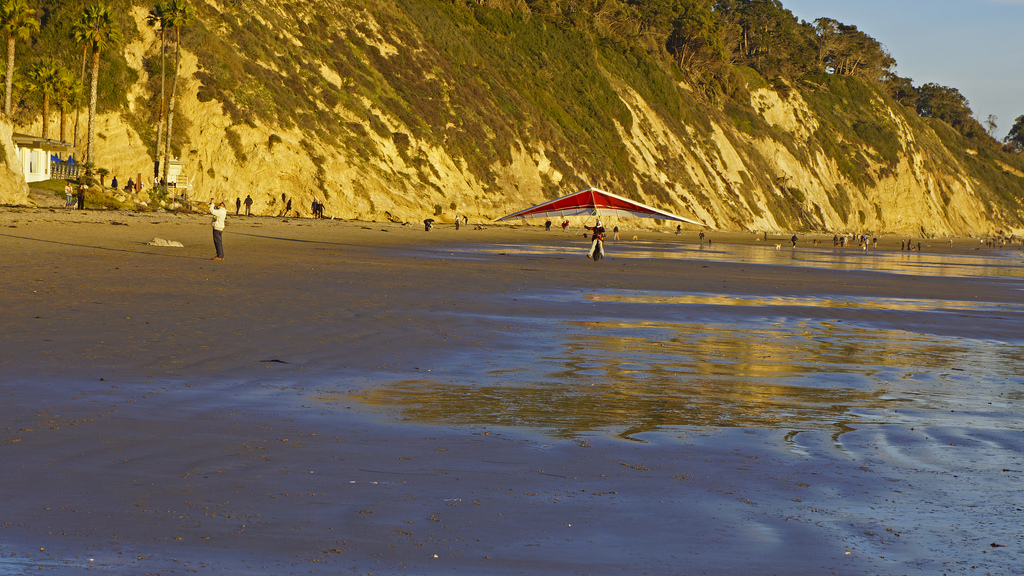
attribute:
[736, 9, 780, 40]
green leaves — on the tree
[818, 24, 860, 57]
green leaves — on the tree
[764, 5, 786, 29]
green leaves — on the tree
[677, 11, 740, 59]
tree leaves — green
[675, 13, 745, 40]
tree leaves — green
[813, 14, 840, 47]
tree leaves — green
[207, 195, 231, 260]
person — standing up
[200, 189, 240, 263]
person — standing up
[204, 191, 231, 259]
person — standing up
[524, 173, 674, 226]
kite — large, red, white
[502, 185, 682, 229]
kite —  red, white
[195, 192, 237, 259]
person — wearing, long , sleeve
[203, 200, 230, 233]
shirt — white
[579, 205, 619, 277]
person —  holding 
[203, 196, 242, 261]
person —  standing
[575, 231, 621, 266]
person —  standing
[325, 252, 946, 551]
water — edge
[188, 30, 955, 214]
cliff — behind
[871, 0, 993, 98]
sky — blue, clear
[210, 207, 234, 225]
shirt — white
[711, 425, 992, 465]
waves — small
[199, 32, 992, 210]
hillside —  reflecting 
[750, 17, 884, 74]
leaves — green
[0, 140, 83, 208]
building —  white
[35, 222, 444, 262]
sand — tan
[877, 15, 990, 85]
sky — blue 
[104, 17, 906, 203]
hillside — yellow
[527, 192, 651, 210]
wing — red ,  white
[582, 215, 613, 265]
person — flying,  white 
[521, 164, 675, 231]
kite — red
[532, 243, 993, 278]
reflection — surface 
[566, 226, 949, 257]
sand — wet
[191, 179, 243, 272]
person — wearing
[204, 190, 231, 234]
shirt — white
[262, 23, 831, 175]
hillside — sandy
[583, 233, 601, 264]
pants — khaki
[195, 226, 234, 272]
pants — dark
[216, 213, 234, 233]
shirt — white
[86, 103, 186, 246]
umbrellas — blue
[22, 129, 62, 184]
building — small and white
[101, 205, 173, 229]
umbrellas — blue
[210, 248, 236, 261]
shoes — brown